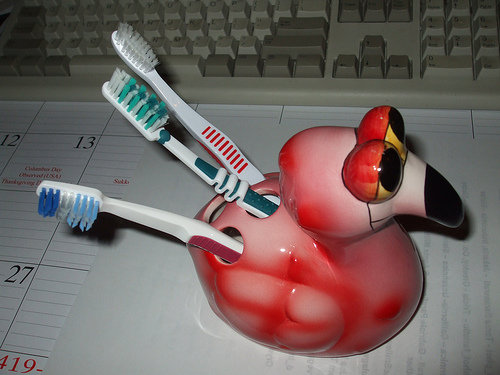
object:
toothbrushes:
[34, 21, 280, 267]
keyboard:
[0, 0, 499, 109]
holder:
[186, 104, 464, 358]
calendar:
[1, 101, 499, 375]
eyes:
[343, 105, 409, 204]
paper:
[40, 116, 500, 375]